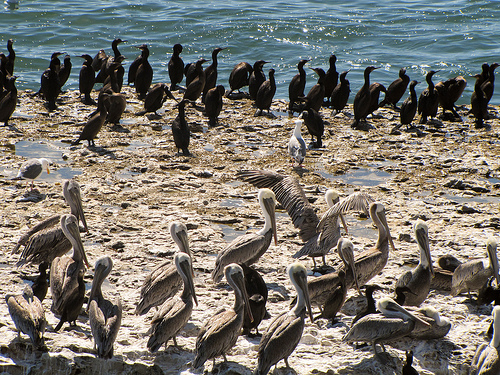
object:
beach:
[141, 171, 210, 184]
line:
[39, 118, 67, 122]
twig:
[347, 131, 359, 136]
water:
[334, 35, 380, 58]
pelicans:
[255, 67, 276, 117]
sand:
[103, 137, 123, 145]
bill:
[121, 39, 129, 42]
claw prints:
[132, 179, 201, 209]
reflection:
[248, 35, 259, 40]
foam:
[455, 16, 478, 38]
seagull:
[142, 252, 200, 352]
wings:
[233, 167, 320, 242]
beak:
[377, 210, 397, 252]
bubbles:
[62, 80, 71, 87]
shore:
[309, 123, 410, 190]